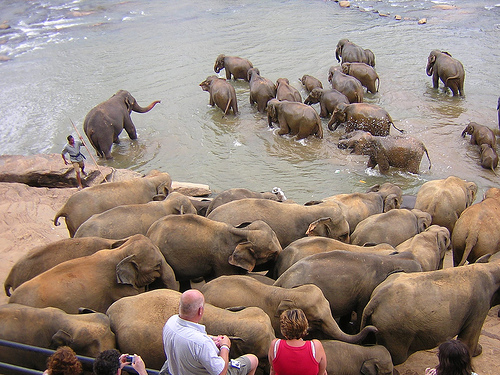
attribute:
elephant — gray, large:
[82, 89, 161, 160]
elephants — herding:
[4, 170, 499, 373]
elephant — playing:
[338, 131, 431, 175]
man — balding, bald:
[163, 288, 259, 374]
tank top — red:
[271, 338, 321, 374]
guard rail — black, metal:
[0, 339, 54, 357]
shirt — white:
[163, 313, 225, 374]